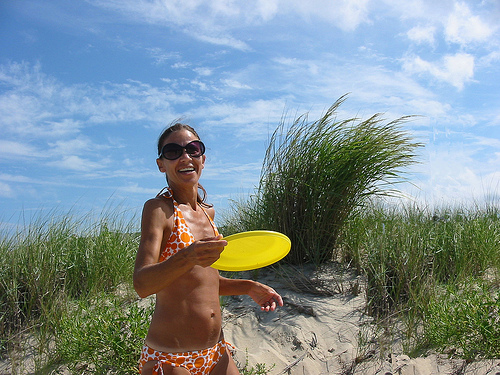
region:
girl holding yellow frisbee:
[120, 112, 268, 374]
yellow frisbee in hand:
[215, 228, 282, 277]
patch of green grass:
[402, 288, 454, 340]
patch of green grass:
[90, 303, 111, 339]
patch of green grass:
[42, 275, 60, 315]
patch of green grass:
[362, 268, 397, 314]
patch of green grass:
[443, 240, 470, 274]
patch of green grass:
[346, 243, 374, 277]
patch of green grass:
[347, 221, 357, 257]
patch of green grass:
[454, 232, 489, 287]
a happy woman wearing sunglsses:
[95, 105, 302, 373]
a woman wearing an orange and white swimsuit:
[81, 94, 311, 371]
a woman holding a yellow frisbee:
[126, 117, 296, 347]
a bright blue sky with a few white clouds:
[0, 2, 496, 187]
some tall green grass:
[240, 88, 435, 288]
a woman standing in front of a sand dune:
[1, 110, 379, 371]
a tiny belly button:
[201, 302, 217, 323]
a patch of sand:
[118, 231, 454, 372]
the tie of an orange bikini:
[143, 347, 169, 372]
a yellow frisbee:
[185, 213, 312, 283]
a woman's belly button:
[205, 303, 219, 323]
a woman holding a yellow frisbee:
[129, 123, 295, 280]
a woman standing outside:
[133, 121, 249, 373]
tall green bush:
[247, 93, 415, 280]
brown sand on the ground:
[8, 253, 495, 373]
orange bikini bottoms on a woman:
[135, 333, 250, 374]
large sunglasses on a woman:
[157, 135, 210, 161]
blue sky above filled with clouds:
[2, 5, 499, 216]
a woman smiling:
[149, 121, 222, 221]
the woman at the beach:
[124, 117, 309, 374]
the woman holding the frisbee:
[103, 102, 349, 369]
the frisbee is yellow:
[194, 233, 304, 281]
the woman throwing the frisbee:
[123, 111, 321, 372]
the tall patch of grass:
[257, 120, 387, 250]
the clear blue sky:
[14, 10, 99, 67]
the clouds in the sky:
[296, 13, 430, 100]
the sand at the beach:
[292, 292, 378, 372]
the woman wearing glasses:
[158, 131, 225, 156]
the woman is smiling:
[171, 160, 203, 178]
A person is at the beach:
[85, 91, 346, 371]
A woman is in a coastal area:
[90, 65, 325, 370]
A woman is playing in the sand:
[80, 80, 345, 365]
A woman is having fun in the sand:
[60, 68, 345, 373]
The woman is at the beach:
[20, 82, 435, 372]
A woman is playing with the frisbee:
[50, 81, 375, 371]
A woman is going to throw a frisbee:
[71, 78, 412, 361]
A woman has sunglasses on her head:
[152, 121, 205, 186]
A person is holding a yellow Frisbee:
[62, 105, 353, 373]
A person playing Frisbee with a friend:
[49, 95, 390, 374]